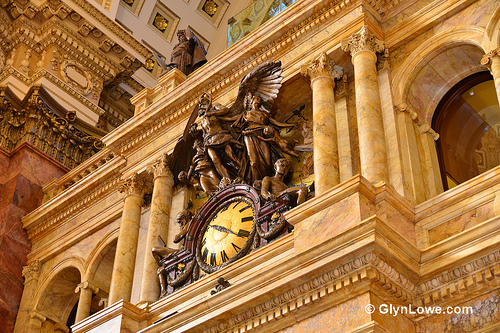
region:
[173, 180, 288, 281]
the clock face is gold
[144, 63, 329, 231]
the statues are brown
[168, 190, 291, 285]
A clock is displayed on a building.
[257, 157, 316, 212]
A statue is sitting on a clock.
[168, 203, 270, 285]
A clock has roman numerals on its face.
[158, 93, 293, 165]
Statues are standing on a clock.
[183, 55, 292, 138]
A statue has wings extended from its body.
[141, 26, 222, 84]
A statue stands on top of the building.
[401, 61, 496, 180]
A window is displayed on a building.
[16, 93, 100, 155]
Gold trim surrounds a building.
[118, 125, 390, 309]
Four pillars stands between a clock.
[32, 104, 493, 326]
Three archeways are designed into the building.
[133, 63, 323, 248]
Statue on top of clock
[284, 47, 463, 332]
Pedestals on side of clock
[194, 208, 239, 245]
Hands on the clock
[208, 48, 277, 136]
Wing on the statue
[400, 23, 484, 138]
Door archway beside statue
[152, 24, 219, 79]
Statue on top of building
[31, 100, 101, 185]
Group of statues on wall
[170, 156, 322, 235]
Statues sitting on top of clock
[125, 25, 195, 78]
Statue holding a sword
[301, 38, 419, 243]
Wall is made of stone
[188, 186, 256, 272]
clock on the building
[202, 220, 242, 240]
minute and hour hand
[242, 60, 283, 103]
wing on a statue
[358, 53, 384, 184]
tall pillar on building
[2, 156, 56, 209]
salmon colored wall of building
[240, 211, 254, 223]
roman numeral 3 on clock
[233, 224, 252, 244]
roman numeral 4 on clock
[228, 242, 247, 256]
roman numeral 5 on clock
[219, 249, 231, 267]
roman numeral 6 on clock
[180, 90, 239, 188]
bronze statue on building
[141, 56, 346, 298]
a large metal sculpture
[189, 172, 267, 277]
a clock under a sculpture.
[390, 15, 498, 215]
An arch inside of a building.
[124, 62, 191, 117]
a pillar inside of a building.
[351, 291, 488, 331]
a water mark on a picture.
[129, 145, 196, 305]
a pillar near a clock.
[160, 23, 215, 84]
a statue inside of a building.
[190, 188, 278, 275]
A gold colored clock.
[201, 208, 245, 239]
clock hands on a clock.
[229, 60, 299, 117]
a wing on a statue.